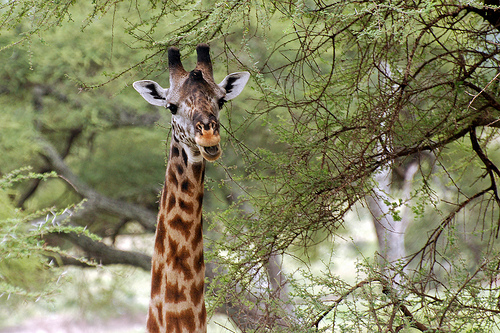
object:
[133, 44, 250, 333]
giraffe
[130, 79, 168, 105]
ears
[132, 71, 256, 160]
giraffe's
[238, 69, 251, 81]
pointed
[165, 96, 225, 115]
two eyes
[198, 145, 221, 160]
open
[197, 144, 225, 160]
mouth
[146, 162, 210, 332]
long neck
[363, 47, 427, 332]
trees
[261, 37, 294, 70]
spindly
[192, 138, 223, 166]
giraffee's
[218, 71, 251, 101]
ear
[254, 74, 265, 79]
leaves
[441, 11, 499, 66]
of picture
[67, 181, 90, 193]
wooden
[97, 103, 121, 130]
background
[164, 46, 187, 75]
horn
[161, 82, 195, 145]
side of his head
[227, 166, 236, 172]
dying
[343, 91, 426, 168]
on branches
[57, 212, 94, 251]
trunk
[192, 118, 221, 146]
above mouth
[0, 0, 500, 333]
picture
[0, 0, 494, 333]
outdoors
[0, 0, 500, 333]
during the day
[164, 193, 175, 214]
brown spots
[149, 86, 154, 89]
are black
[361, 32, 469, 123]
among tree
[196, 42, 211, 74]
horns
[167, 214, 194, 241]
spot